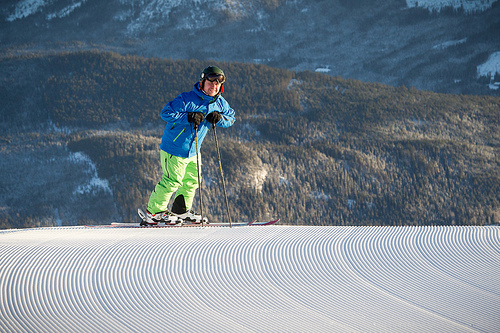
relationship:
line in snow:
[219, 219, 289, 305] [131, 233, 479, 304]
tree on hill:
[262, 89, 445, 156] [233, 4, 495, 127]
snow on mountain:
[131, 233, 479, 304] [26, 35, 498, 253]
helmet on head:
[189, 60, 249, 92] [181, 54, 243, 96]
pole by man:
[191, 119, 219, 237] [145, 66, 235, 225]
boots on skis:
[146, 201, 211, 229] [78, 214, 313, 231]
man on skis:
[127, 39, 244, 225] [78, 214, 313, 231]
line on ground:
[219, 219, 289, 305] [30, 211, 455, 314]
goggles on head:
[204, 68, 228, 84] [181, 54, 243, 96]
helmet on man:
[189, 60, 249, 92] [127, 39, 244, 225]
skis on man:
[78, 214, 313, 231] [127, 39, 244, 225]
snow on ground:
[131, 233, 479, 304] [30, 211, 455, 314]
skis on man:
[78, 214, 313, 231] [145, 66, 235, 225]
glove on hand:
[197, 106, 239, 131] [207, 106, 223, 121]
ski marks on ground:
[2, 226, 481, 330] [30, 211, 455, 314]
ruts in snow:
[3, 225, 483, 328] [131, 233, 479, 304]